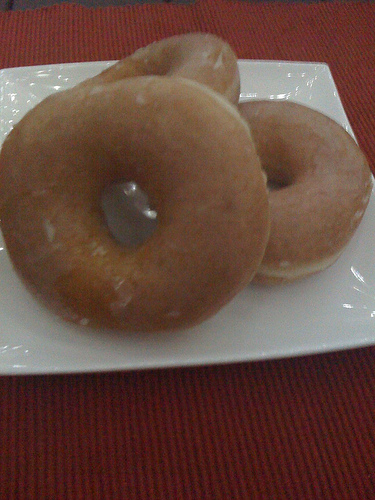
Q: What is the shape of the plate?
A: A square.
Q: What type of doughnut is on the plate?
A: A glazed doughnut.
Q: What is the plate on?
A: A red placemat.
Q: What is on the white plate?
A: Three doughnuts.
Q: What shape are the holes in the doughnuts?
A: A circle.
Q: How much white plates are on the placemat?
A: One.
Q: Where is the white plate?
A: On the red cloth.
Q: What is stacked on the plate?
A: Doughnuts.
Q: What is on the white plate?
A: Doughnuts.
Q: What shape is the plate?
A: Square.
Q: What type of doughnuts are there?
A: Glazed.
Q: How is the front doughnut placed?
A: Upright.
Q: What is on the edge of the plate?
A: Doughnut.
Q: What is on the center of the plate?
A: Doughnut.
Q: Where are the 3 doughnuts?
A: On plate.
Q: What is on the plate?
A: Donuts.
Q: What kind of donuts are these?
A: Glazed.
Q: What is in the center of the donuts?
A: A hole.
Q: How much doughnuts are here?
A: 3.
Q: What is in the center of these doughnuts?
A: Holes.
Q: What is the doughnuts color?
A: Tannish brown.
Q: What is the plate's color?
A: White.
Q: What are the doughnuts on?
A: Plate.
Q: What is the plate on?
A: A table cloth.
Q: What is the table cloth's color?
A: Red.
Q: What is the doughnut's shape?
A: Round.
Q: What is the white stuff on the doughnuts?
A: Glazed.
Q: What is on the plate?
A: Donuts.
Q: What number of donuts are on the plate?
A: 3.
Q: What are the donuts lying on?
A: Plate.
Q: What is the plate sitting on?
A: Table.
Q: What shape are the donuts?
A: Round.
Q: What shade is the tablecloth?
A: Red.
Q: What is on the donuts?
A: Glaze.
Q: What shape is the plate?
A: Square.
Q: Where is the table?
A: In the house.